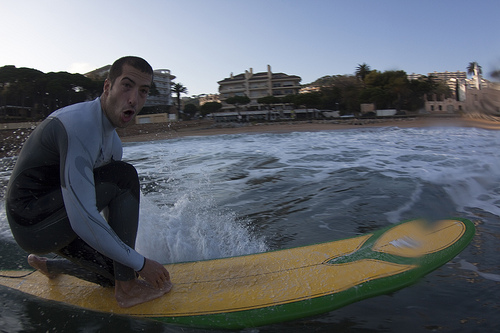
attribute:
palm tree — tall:
[354, 61, 371, 84]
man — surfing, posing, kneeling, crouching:
[8, 55, 165, 307]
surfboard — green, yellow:
[6, 210, 484, 330]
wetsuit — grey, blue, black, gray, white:
[4, 100, 165, 280]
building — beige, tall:
[209, 70, 304, 117]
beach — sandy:
[125, 111, 485, 137]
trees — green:
[326, 78, 439, 103]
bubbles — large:
[144, 172, 269, 230]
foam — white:
[261, 140, 490, 176]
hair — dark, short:
[109, 56, 153, 81]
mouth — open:
[121, 107, 137, 123]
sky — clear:
[2, 2, 499, 67]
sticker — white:
[389, 233, 422, 253]